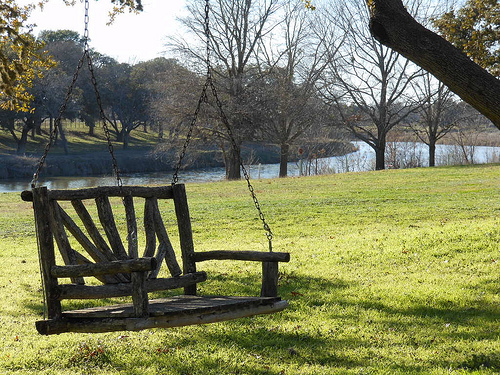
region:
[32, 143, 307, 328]
the seat is made of wood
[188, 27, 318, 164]
the trees are bare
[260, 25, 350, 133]
the trees are bare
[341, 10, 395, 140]
the trees are bare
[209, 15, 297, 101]
the trees are bare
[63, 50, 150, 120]
trees in the distance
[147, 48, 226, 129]
trees in the distance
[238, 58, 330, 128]
trees in the distance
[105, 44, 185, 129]
trees in the distance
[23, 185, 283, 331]
A swinging chair above the grass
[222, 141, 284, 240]
A chain holding the chair up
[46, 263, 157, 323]
The chair is made of wood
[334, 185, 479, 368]
Grass by the swinging chair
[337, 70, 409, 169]
A bare tree by the river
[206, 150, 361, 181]
A river behind the swinging chair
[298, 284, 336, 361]
Shadows on the ground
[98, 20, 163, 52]
The sky above the trees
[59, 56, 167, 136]
Trees across the river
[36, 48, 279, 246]
The chains holding on to the chair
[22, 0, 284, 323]
swing seat hanging from tree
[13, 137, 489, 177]
small river in background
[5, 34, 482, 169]
tree line in a forest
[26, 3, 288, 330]
swing seat under shade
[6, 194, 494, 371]
grassy field during autumn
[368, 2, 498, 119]
brown tree branch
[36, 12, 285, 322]
wooden swing hanging from tree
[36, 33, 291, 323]
old wooden swing on tree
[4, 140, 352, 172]
long river bank in background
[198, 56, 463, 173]
dry trees near river bank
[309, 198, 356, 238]
grass on the ground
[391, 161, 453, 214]
grass on the ground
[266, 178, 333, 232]
grass on the ground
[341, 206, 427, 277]
grass on the ground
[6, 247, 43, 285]
grass on the ground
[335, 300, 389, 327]
shadows on the ground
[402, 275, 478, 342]
shadows on the ground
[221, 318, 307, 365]
shadows on the ground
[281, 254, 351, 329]
shadows on the ground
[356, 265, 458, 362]
shadows on the ground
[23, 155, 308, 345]
Bench chained up to a tree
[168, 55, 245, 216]
Chains on a wooden post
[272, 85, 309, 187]
tree in the park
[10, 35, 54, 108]
leaves on a tree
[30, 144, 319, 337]
wooden bench hanging from a tree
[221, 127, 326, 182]
pond in a park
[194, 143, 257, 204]
water in front of a tree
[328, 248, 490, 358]
shadow of a tree on the ground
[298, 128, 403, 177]
water running through the park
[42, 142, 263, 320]
hammock in the sky